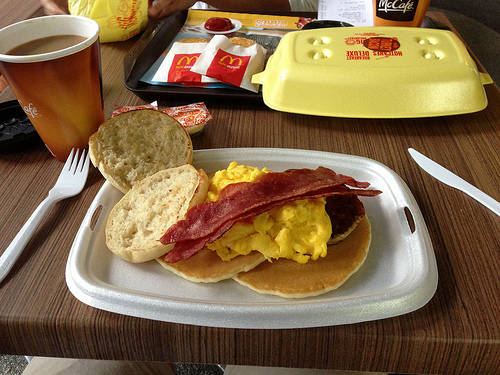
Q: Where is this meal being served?
A: McDonalds.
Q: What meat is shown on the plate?
A: Bacon.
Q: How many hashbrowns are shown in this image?
A: Two.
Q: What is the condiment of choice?
A: Ketchup.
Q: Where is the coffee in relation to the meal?
A: Left.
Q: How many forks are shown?
A: One.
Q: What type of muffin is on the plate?
A: English.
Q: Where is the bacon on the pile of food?
A: Top.